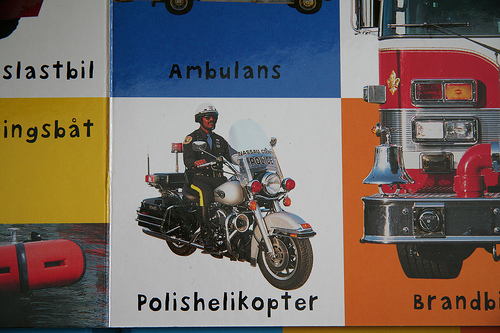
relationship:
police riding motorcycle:
[181, 102, 249, 251] [133, 117, 316, 290]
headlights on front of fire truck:
[412, 115, 478, 144] [349, 0, 498, 280]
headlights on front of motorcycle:
[249, 172, 296, 194] [133, 117, 316, 290]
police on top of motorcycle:
[181, 102, 249, 251] [133, 117, 316, 290]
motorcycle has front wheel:
[133, 117, 316, 290] [256, 232, 313, 290]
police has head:
[181, 102, 249, 251] [194, 102, 221, 132]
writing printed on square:
[2, 116, 96, 142] [1, 97, 110, 224]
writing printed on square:
[133, 285, 321, 318] [110, 96, 343, 329]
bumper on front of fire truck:
[359, 189, 499, 249] [349, 0, 498, 280]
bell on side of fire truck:
[358, 125, 412, 196] [349, 0, 498, 280]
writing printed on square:
[411, 289, 499, 312] [341, 99, 498, 328]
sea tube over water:
[2, 226, 86, 303] [0, 224, 108, 327]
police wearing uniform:
[181, 102, 249, 251] [182, 128, 244, 249]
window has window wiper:
[379, 0, 498, 36] [382, 22, 499, 55]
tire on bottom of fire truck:
[395, 243, 463, 282] [349, 0, 498, 280]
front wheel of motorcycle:
[256, 232, 313, 290] [133, 117, 316, 290]